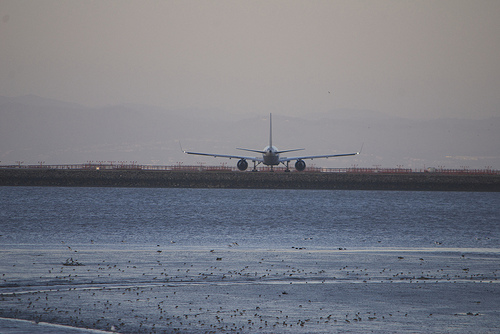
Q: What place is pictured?
A: It is a beach.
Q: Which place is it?
A: It is a beach.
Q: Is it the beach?
A: Yes, it is the beach.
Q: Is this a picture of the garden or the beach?
A: It is showing the beach.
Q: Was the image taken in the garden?
A: No, the picture was taken in the beach.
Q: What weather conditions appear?
A: It is foggy.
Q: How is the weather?
A: It is foggy.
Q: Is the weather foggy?
A: Yes, it is foggy.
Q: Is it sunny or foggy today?
A: It is foggy.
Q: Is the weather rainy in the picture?
A: No, it is foggy.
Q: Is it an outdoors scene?
A: Yes, it is outdoors.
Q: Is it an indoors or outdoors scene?
A: It is outdoors.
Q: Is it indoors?
A: No, it is outdoors.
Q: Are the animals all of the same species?
A: Yes, all the animals are birds.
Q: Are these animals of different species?
A: No, all the animals are birds.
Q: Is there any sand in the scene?
A: Yes, there is sand.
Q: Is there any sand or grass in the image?
A: Yes, there is sand.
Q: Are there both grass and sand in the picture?
A: No, there is sand but no grass.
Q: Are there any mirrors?
A: No, there are no mirrors.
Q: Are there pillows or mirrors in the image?
A: No, there are no mirrors or pillows.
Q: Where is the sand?
A: The sand is on the beach.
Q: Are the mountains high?
A: Yes, the mountains are high.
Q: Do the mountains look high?
A: Yes, the mountains are high.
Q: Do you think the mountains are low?
A: No, the mountains are high.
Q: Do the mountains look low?
A: No, the mountains are high.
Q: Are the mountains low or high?
A: The mountains are high.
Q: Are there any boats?
A: No, there are no boats.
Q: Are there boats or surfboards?
A: No, there are no boats or surfboards.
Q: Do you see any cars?
A: No, there are no cars.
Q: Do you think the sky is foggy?
A: Yes, the sky is foggy.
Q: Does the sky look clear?
A: No, the sky is foggy.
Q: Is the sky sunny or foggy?
A: The sky is foggy.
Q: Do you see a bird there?
A: Yes, there are birds.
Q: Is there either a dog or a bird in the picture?
A: Yes, there are birds.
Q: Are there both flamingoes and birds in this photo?
A: No, there are birds but no flamingoes.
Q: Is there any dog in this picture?
A: No, there are no dogs.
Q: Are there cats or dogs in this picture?
A: No, there are no dogs or cats.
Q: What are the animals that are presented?
A: The animals are birds.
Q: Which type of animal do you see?
A: The animal is birds.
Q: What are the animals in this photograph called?
A: The animals are birds.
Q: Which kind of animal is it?
A: The animals are birds.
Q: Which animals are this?
A: These are birds.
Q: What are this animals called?
A: These are birds.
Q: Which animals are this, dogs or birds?
A: These are birds.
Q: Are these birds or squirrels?
A: These are birds.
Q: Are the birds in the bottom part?
A: Yes, the birds are in the bottom of the image.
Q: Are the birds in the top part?
A: No, the birds are in the bottom of the image.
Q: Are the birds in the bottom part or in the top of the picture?
A: The birds are in the bottom of the image.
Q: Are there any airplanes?
A: Yes, there is an airplane.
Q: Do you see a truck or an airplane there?
A: Yes, there is an airplane.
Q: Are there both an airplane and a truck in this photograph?
A: No, there is an airplane but no trucks.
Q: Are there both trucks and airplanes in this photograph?
A: No, there is an airplane but no trucks.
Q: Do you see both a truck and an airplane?
A: No, there is an airplane but no trucks.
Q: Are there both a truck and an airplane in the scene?
A: No, there is an airplane but no trucks.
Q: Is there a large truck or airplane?
A: Yes, there is a large airplane.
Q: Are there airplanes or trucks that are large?
A: Yes, the airplane is large.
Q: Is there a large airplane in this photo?
A: Yes, there is a large airplane.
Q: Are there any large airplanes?
A: Yes, there is a large airplane.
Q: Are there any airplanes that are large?
A: Yes, there is an airplane that is large.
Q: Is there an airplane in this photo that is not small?
A: Yes, there is a large airplane.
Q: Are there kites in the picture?
A: No, there are no kites.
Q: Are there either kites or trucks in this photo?
A: No, there are no kites or trucks.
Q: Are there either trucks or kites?
A: No, there are no kites or trucks.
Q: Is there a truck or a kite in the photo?
A: No, there are no kites or trucks.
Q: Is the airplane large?
A: Yes, the airplane is large.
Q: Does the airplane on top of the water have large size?
A: Yes, the airplane is large.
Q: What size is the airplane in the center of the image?
A: The plane is large.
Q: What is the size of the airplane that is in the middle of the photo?
A: The plane is large.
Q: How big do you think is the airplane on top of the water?
A: The airplane is large.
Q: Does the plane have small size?
A: No, the plane is large.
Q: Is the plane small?
A: No, the plane is large.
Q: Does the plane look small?
A: No, the plane is large.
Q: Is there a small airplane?
A: No, there is an airplane but it is large.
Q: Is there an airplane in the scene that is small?
A: No, there is an airplane but it is large.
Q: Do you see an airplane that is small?
A: No, there is an airplane but it is large.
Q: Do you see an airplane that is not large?
A: No, there is an airplane but it is large.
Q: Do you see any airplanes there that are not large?
A: No, there is an airplane but it is large.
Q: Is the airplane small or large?
A: The airplane is large.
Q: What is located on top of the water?
A: The plane is on top of the water.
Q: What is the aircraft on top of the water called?
A: The aircraft is an airplane.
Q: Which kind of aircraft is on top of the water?
A: The aircraft is an airplane.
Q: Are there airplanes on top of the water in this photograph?
A: Yes, there is an airplane on top of the water.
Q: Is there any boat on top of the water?
A: No, there is an airplane on top of the water.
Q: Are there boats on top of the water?
A: No, there is an airplane on top of the water.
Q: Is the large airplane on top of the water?
A: Yes, the airplane is on top of the water.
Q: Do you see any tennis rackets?
A: No, there are no tennis rackets.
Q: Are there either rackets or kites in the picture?
A: No, there are no rackets or kites.